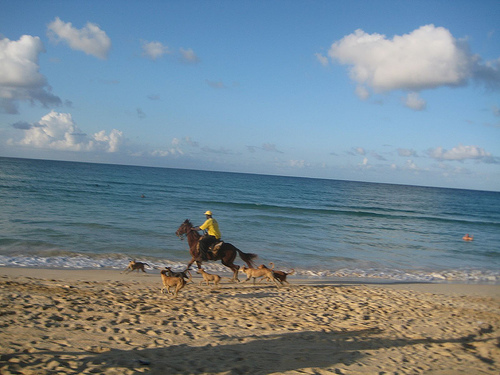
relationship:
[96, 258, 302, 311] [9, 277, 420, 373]
dogs running on beach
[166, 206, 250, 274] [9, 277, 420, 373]
horse running on beach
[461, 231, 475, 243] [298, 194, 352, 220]
man in ocean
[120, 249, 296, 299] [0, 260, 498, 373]
dogs running on beach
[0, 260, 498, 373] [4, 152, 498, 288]
beach near ocean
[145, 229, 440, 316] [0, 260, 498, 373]
dogs on beach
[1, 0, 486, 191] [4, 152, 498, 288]
skies over ocean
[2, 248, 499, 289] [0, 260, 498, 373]
tide water rolling onto beach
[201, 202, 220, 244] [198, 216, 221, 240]
man in shirt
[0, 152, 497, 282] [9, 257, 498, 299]
ocean coming on shore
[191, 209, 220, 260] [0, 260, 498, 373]
man galloping on beach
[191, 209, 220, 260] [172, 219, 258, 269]
man riding horse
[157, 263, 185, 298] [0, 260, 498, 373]
dog running on beach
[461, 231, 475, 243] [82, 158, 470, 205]
man swimming in ocean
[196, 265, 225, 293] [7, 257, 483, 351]
dog running on sand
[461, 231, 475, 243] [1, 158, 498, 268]
man swimming in ocean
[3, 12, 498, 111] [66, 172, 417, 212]
clouds over ocean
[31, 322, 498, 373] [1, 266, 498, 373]
shadow on sand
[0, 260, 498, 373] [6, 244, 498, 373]
beach in beach